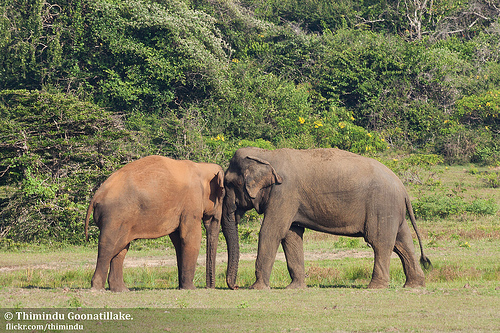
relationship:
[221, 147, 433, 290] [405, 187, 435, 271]
elephant has tail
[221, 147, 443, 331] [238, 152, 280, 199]
elephant has ear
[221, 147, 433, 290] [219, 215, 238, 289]
elephant has trunk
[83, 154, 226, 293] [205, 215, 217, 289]
elephant has trunk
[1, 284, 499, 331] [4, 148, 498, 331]
grass in field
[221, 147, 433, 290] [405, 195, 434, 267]
elephant has tail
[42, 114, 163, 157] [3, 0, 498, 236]
stick in mountain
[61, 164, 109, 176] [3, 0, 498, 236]
stick in mountain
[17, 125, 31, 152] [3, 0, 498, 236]
stick in mountain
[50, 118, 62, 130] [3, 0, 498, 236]
stick in mountain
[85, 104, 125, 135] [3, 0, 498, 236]
stick in mountain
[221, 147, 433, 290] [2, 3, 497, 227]
elephant in wild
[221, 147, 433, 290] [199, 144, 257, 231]
elephant touching heads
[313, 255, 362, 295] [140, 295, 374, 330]
grass on ground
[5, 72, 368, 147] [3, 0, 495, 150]
bushes in background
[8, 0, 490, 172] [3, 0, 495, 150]
trees in background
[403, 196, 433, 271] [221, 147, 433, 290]
tail of elephant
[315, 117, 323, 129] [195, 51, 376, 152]
flower on tree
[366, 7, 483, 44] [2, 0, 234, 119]
banches on tree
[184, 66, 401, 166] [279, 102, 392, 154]
bush with flowers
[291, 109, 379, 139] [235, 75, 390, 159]
flowers adorn bush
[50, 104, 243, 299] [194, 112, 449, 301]
elephant standing with elephant